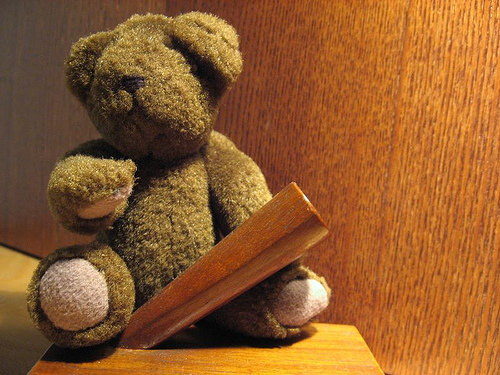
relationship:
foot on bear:
[25, 246, 134, 349] [26, 13, 334, 351]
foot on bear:
[263, 266, 343, 345] [26, 13, 334, 351]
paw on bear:
[69, 162, 135, 221] [26, 13, 334, 351]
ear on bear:
[65, 31, 109, 85] [26, 13, 334, 351]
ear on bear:
[164, 12, 249, 87] [26, 13, 334, 351]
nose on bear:
[116, 74, 147, 93] [26, 13, 334, 351]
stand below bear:
[23, 322, 385, 374] [26, 13, 334, 351]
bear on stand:
[26, 13, 334, 351] [23, 322, 385, 374]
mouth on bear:
[122, 106, 161, 130] [26, 13, 334, 351]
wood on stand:
[119, 177, 333, 352] [23, 322, 385, 374]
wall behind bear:
[247, 0, 500, 374] [26, 13, 334, 351]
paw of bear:
[69, 162, 135, 221] [26, 13, 334, 351]